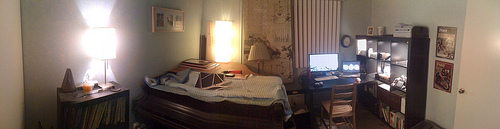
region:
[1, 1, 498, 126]
a home office room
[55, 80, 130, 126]
a brown wooden bookcase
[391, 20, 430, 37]
a white printer on top of a bookshelf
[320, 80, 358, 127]
a chair in front of the desk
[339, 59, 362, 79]
a laptop computer on the desk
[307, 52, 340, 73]
a monitor on top of a desk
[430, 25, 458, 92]
two posters on the wall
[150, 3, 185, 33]
a picture on the wall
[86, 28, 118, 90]
a lamp on top of a bookcase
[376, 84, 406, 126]
books on the shelves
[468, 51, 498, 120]
A white house wall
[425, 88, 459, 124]
A white house wall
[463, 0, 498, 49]
A white house wall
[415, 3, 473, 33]
A white house wall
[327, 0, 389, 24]
A white house wall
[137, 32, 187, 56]
A white house wall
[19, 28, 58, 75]
A white house wall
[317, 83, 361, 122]
A wooden arm chair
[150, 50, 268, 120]
A poorly spread bed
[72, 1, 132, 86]
A sharp light from the window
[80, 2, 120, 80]
lights bright on wall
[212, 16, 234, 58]
lights bright on wall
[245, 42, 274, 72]
lamp unlit by wall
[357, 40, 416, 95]
lights shining in bookshelf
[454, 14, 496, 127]
closed white door for room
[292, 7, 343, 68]
striped wall behind computer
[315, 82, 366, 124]
chair under computer desk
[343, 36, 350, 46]
clock on wall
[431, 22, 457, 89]
posters hanging on wall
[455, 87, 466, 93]
handle of white door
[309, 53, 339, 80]
computer turned on on desk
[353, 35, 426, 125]
brown shelf with square shelving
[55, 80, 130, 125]
small brown bookcase next to piano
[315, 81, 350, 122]
brown wooden chair with cushion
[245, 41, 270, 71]
old turned off lamp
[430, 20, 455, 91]
red and gray posters on wall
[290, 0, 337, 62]
white vertical blinds on window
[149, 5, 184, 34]
frame on wall with three pictures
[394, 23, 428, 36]
printer on top of shelf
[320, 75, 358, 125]
a wooden desk chair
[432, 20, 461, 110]
two posters on the wall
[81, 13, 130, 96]
a brightly lit table lamp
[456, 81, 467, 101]
knob on the white door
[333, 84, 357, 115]
the back of the desk chair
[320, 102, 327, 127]
the front left chair leg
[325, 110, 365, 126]
the back chair legs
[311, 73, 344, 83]
the keyboard that is connected to the computer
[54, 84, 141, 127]
a wooden bookself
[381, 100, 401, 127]
books on the bottom of the shelf